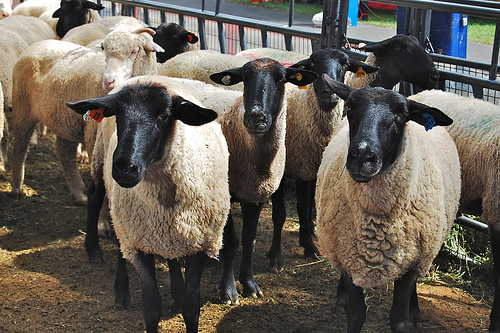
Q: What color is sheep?
A: White and black.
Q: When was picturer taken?
A: Daytime.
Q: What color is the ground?
A: Brown.